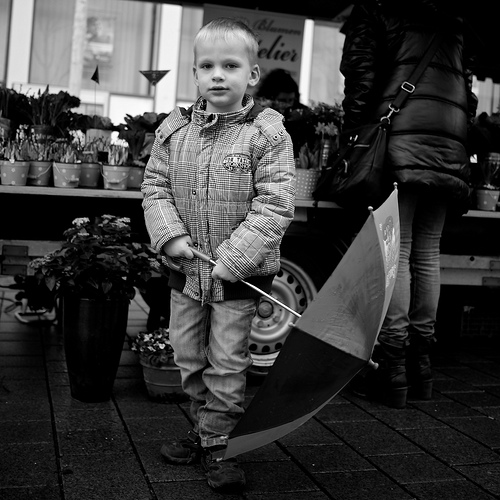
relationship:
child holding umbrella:
[138, 13, 304, 495] [176, 173, 408, 465]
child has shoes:
[138, 13, 304, 495] [163, 427, 251, 492]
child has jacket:
[138, 13, 304, 495] [137, 102, 291, 302]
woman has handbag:
[324, 1, 478, 351] [317, 114, 395, 204]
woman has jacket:
[324, 1, 478, 351] [339, 1, 481, 213]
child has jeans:
[138, 13, 304, 495] [170, 290, 258, 440]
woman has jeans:
[324, 1, 478, 351] [397, 187, 453, 342]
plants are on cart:
[2, 85, 142, 188] [4, 182, 141, 263]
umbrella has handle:
[176, 173, 408, 465] [165, 242, 305, 319]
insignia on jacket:
[222, 149, 256, 178] [137, 102, 291, 302]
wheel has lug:
[228, 224, 348, 393] [257, 298, 277, 323]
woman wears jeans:
[324, 1, 478, 351] [397, 187, 453, 342]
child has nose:
[138, 13, 304, 495] [209, 70, 228, 84]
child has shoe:
[138, 13, 304, 495] [204, 442, 250, 495]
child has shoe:
[138, 13, 304, 495] [158, 424, 205, 470]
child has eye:
[138, 13, 304, 495] [219, 59, 244, 75]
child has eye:
[138, 13, 304, 495] [194, 59, 216, 75]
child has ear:
[138, 13, 304, 495] [246, 62, 264, 91]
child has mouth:
[138, 13, 304, 495] [202, 83, 234, 97]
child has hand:
[138, 13, 304, 495] [157, 232, 199, 262]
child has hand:
[138, 13, 304, 495] [209, 259, 243, 290]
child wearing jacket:
[138, 13, 304, 495] [137, 102, 291, 302]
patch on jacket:
[222, 149, 256, 178] [137, 102, 291, 302]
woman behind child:
[324, 1, 478, 351] [138, 13, 304, 495]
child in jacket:
[138, 13, 304, 495] [137, 102, 291, 302]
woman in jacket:
[324, 1, 478, 351] [339, 1, 481, 213]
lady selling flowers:
[259, 68, 312, 113] [2, 85, 142, 188]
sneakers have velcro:
[163, 427, 251, 492] [205, 445, 226, 462]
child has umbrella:
[138, 13, 304, 495] [176, 173, 408, 465]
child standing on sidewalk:
[138, 13, 304, 495] [2, 308, 499, 499]